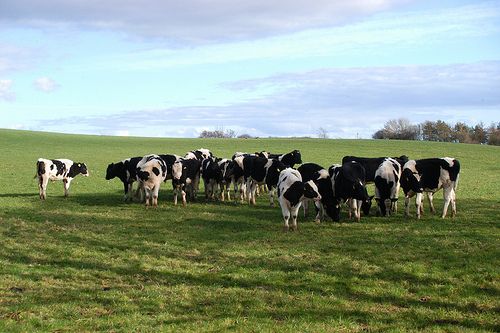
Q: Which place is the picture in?
A: It is at the field.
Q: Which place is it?
A: It is a field.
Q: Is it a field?
A: Yes, it is a field.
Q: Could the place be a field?
A: Yes, it is a field.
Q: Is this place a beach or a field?
A: It is a field.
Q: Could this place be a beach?
A: No, it is a field.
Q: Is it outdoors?
A: Yes, it is outdoors.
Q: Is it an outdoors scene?
A: Yes, it is outdoors.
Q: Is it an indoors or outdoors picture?
A: It is outdoors.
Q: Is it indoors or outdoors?
A: It is outdoors.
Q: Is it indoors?
A: No, it is outdoors.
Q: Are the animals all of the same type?
A: Yes, all the animals are cows.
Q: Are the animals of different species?
A: No, all the animals are cows.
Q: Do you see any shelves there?
A: No, there are no shelves.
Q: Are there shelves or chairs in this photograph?
A: No, there are no shelves or chairs.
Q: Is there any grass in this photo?
A: Yes, there is grass.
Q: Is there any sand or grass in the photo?
A: Yes, there is grass.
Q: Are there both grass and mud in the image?
A: No, there is grass but no mud.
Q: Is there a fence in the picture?
A: No, there are no fences.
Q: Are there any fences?
A: No, there are no fences.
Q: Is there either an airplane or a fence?
A: No, there are no fences or airplanes.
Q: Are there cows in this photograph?
A: Yes, there is a cow.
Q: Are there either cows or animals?
A: Yes, there is a cow.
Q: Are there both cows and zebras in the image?
A: No, there is a cow but no zebras.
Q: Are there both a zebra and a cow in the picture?
A: No, there is a cow but no zebras.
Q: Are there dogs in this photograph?
A: No, there are no dogs.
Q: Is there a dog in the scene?
A: No, there are no dogs.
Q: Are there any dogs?
A: No, there are no dogs.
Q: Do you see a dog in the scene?
A: No, there are no dogs.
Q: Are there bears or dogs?
A: No, there are no dogs or bears.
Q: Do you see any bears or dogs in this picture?
A: No, there are no dogs or bears.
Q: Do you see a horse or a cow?
A: Yes, there is a cow.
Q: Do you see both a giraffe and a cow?
A: No, there is a cow but no giraffes.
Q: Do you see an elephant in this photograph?
A: No, there are no elephants.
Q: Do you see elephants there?
A: No, there are no elephants.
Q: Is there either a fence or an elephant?
A: No, there are no elephants or fences.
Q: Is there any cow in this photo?
A: Yes, there is a cow.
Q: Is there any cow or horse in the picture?
A: Yes, there is a cow.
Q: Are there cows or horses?
A: Yes, there is a cow.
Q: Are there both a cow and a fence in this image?
A: No, there is a cow but no fences.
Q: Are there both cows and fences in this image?
A: No, there is a cow but no fences.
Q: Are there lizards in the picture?
A: No, there are no lizards.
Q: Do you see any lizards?
A: No, there are no lizards.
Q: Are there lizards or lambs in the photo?
A: No, there are no lizards or lambs.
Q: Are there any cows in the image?
A: Yes, there is a cow.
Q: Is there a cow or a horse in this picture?
A: Yes, there is a cow.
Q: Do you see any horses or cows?
A: Yes, there is a cow.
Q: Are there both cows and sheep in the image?
A: No, there is a cow but no sheep.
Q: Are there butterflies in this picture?
A: No, there are no butterflies.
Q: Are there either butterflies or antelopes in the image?
A: No, there are no butterflies or antelopes.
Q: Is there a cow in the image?
A: Yes, there is a cow.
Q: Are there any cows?
A: Yes, there is a cow.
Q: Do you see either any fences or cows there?
A: Yes, there is a cow.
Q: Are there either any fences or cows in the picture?
A: Yes, there is a cow.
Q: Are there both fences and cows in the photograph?
A: No, there is a cow but no fences.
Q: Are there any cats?
A: No, there are no cats.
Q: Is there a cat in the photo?
A: No, there are no cats.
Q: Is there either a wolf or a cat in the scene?
A: No, there are no cats or wolves.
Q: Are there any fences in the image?
A: No, there are no fences.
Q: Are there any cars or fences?
A: No, there are no fences or cars.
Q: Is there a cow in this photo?
A: Yes, there is a cow.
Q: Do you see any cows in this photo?
A: Yes, there is a cow.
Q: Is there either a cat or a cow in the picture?
A: Yes, there is a cow.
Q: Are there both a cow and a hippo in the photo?
A: No, there is a cow but no hippos.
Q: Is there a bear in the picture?
A: No, there are no bears.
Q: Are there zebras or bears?
A: No, there are no bears or zebras.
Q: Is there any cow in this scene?
A: Yes, there is a cow.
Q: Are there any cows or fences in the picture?
A: Yes, there is a cow.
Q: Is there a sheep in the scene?
A: No, there is no sheep.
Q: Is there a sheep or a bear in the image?
A: No, there are no sheep or bears.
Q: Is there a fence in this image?
A: No, there are no fences.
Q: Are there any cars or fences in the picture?
A: No, there are no fences or cars.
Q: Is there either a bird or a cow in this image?
A: Yes, there is a cow.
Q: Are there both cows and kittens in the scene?
A: No, there is a cow but no kittens.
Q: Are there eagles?
A: No, there are no eagles.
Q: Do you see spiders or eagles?
A: No, there are no eagles or spiders.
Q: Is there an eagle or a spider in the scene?
A: No, there are no eagles or spiders.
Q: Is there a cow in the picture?
A: Yes, there is a cow.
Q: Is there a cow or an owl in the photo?
A: Yes, there is a cow.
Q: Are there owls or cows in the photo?
A: Yes, there is a cow.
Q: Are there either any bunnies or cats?
A: No, there are no cats or bunnies.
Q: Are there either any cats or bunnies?
A: No, there are no cats or bunnies.